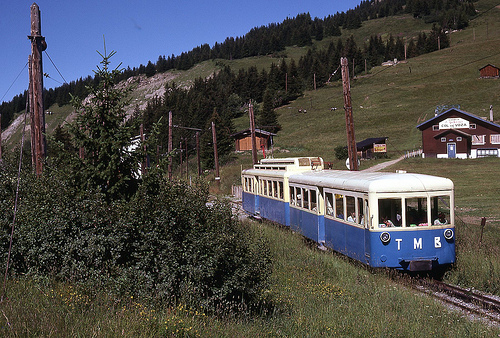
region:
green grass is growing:
[296, 255, 321, 282]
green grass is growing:
[101, 284, 129, 324]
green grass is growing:
[388, 305, 402, 333]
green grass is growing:
[145, 308, 169, 330]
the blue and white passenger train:
[242, 155, 456, 278]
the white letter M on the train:
[242, 156, 456, 275]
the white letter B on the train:
[242, 156, 456, 283]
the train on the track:
[207, 156, 499, 323]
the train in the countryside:
[0, 0, 499, 337]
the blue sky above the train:
[0, 0, 498, 335]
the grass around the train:
[1, 0, 498, 337]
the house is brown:
[415, 99, 496, 171]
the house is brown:
[410, 98, 490, 169]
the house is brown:
[409, 99, 496, 186]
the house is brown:
[415, 98, 489, 188]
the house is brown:
[400, 100, 480, 162]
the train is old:
[233, 157, 453, 284]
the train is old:
[225, 137, 472, 317]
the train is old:
[229, 145, 479, 295]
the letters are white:
[390, 237, 450, 260]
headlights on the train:
[377, 229, 457, 242]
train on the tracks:
[243, 155, 448, 291]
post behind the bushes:
[20, 60, 261, 325]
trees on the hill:
[142, 37, 443, 128]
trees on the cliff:
[45, 55, 267, 93]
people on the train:
[290, 187, 440, 233]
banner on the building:
[436, 117, 467, 128]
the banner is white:
[440, 120, 475, 130]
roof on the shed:
[236, 123, 267, 140]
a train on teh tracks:
[227, 138, 457, 288]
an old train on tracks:
[247, 130, 485, 319]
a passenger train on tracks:
[255, 143, 474, 272]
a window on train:
[379, 199, 397, 230]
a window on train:
[402, 198, 430, 227]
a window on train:
[430, 194, 447, 223]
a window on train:
[346, 192, 357, 219]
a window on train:
[330, 195, 340, 220]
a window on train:
[309, 188, 315, 203]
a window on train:
[290, 183, 312, 205]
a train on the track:
[269, 130, 499, 273]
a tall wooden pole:
[321, 40, 391, 195]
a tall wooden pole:
[237, 101, 257, 151]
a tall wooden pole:
[214, 111, 231, 190]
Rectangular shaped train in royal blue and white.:
[239, 153, 456, 272]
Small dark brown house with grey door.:
[417, 105, 499, 156]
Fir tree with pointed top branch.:
[53, 33, 173, 195]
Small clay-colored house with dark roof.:
[232, 127, 272, 152]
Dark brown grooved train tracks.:
[395, 273, 499, 325]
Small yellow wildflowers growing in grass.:
[54, 290, 207, 335]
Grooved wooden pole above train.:
[337, 55, 359, 169]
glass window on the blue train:
[375, 195, 404, 227]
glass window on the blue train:
[403, 193, 428, 228]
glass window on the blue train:
[428, 194, 452, 226]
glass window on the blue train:
[357, 196, 367, 226]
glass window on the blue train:
[277, 178, 286, 200]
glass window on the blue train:
[342, 192, 355, 222]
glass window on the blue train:
[332, 190, 342, 217]